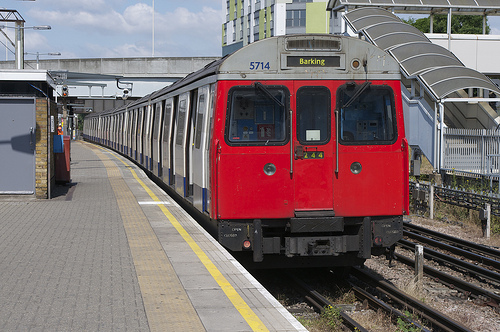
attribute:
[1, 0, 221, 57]
sky — blue, white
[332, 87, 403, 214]
doors — red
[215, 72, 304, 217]
doors — red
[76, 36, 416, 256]
train — red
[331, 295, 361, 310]
grass — brown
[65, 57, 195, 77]
bridge — grey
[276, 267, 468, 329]
tracks — brown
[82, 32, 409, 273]
train — red, silver, grey